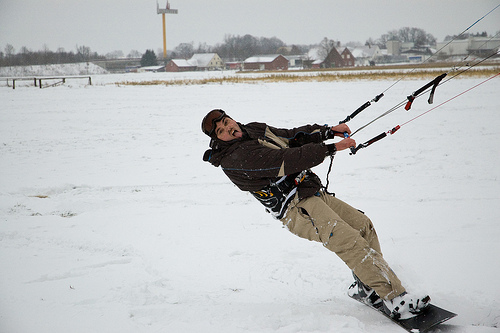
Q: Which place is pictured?
A: It is a field.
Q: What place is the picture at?
A: It is at the field.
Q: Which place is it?
A: It is a field.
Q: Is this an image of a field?
A: Yes, it is showing a field.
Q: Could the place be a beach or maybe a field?
A: It is a field.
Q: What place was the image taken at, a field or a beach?
A: It was taken at a field.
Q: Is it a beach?
A: No, it is a field.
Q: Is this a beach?
A: No, it is a field.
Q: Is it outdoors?
A: Yes, it is outdoors.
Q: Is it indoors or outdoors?
A: It is outdoors.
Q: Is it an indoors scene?
A: No, it is outdoors.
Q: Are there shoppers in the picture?
A: No, there are no shoppers.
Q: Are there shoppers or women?
A: No, there are no shoppers or women.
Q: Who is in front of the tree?
A: The man is in front of the tree.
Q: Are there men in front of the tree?
A: Yes, there is a man in front of the tree.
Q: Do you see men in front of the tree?
A: Yes, there is a man in front of the tree.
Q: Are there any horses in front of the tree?
A: No, there is a man in front of the tree.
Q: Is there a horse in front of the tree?
A: No, there is a man in front of the tree.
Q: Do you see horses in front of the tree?
A: No, there is a man in front of the tree.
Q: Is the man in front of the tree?
A: Yes, the man is in front of the tree.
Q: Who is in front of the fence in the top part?
A: The man is in front of the fence.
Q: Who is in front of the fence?
A: The man is in front of the fence.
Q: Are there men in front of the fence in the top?
A: Yes, there is a man in front of the fence.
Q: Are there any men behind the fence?
A: No, the man is in front of the fence.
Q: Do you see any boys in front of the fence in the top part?
A: No, there is a man in front of the fence.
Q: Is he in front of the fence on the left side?
A: Yes, the man is in front of the fence.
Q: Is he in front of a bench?
A: No, the man is in front of the fence.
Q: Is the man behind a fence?
A: No, the man is in front of a fence.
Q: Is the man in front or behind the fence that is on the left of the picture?
A: The man is in front of the fence.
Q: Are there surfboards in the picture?
A: No, there are no surfboards.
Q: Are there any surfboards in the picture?
A: No, there are no surfboards.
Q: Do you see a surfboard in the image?
A: No, there are no surfboards.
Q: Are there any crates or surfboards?
A: No, there are no surfboards or crates.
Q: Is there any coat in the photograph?
A: Yes, there is a coat.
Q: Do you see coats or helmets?
A: Yes, there is a coat.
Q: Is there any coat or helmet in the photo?
A: Yes, there is a coat.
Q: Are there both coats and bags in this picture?
A: No, there is a coat but no bags.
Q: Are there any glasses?
A: No, there are no glasses.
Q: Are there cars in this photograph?
A: No, there are no cars.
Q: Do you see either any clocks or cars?
A: No, there are no cars or clocks.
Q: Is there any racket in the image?
A: No, there are no rackets.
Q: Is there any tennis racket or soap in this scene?
A: No, there are no rackets or soaps.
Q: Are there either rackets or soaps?
A: No, there are no rackets or soaps.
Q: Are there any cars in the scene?
A: No, there are no cars.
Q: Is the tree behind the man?
A: Yes, the tree is behind the man.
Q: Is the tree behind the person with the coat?
A: Yes, the tree is behind the man.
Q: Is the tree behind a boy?
A: No, the tree is behind the man.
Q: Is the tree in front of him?
A: No, the tree is behind a man.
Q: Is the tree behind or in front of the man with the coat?
A: The tree is behind the man.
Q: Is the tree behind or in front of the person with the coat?
A: The tree is behind the man.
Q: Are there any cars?
A: No, there are no cars.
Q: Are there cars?
A: No, there are no cars.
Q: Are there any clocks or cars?
A: No, there are no cars or clocks.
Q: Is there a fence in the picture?
A: Yes, there is a fence.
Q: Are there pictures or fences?
A: Yes, there is a fence.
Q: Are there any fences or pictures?
A: Yes, there is a fence.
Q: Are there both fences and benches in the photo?
A: No, there is a fence but no benches.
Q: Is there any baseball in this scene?
A: No, there are no baseballs.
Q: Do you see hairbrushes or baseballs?
A: No, there are no baseballs or hairbrushes.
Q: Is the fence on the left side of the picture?
A: Yes, the fence is on the left of the image.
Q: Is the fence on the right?
A: No, the fence is on the left of the image.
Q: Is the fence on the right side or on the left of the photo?
A: The fence is on the left of the image.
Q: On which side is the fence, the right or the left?
A: The fence is on the left of the image.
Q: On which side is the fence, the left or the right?
A: The fence is on the left of the image.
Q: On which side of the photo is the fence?
A: The fence is on the left of the image.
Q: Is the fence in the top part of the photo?
A: Yes, the fence is in the top of the image.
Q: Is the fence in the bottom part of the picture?
A: No, the fence is in the top of the image.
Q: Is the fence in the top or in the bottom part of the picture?
A: The fence is in the top of the image.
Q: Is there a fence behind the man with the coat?
A: Yes, there is a fence behind the man.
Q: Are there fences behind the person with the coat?
A: Yes, there is a fence behind the man.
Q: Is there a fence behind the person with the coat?
A: Yes, there is a fence behind the man.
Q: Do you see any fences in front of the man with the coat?
A: No, the fence is behind the man.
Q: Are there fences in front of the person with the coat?
A: No, the fence is behind the man.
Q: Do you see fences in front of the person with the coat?
A: No, the fence is behind the man.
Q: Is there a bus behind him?
A: No, there is a fence behind the man.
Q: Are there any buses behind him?
A: No, there is a fence behind the man.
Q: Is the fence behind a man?
A: Yes, the fence is behind a man.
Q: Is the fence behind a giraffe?
A: No, the fence is behind a man.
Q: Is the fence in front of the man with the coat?
A: No, the fence is behind the man.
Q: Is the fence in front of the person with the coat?
A: No, the fence is behind the man.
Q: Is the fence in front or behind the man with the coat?
A: The fence is behind the man.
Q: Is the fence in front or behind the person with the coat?
A: The fence is behind the man.